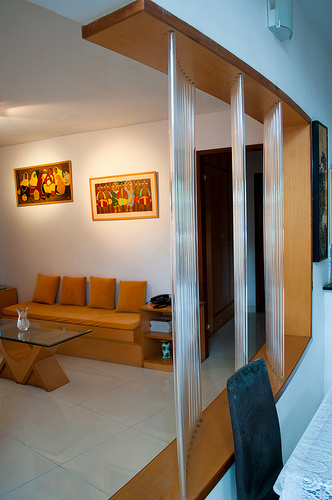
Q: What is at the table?
A: A chair.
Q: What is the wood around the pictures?
A: Frames.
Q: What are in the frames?
A: Pictures.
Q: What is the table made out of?
A: Glass.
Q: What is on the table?
A: Vase.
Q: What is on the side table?
A: Telephone.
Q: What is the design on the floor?
A: Tile.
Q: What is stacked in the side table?
A: Magazines.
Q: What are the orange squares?
A: Pillows.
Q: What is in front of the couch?
A: Table.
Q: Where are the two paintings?
A: On the wall.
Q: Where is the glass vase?
A: Coffee table.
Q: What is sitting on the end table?
A: Telephone.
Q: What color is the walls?
A: The walls are white.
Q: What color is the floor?
A: The floor is white.